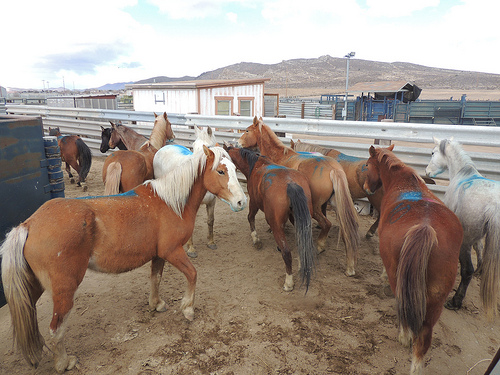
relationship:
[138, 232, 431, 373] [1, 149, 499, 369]
footprints in dirt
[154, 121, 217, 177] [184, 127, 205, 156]
horse has light hair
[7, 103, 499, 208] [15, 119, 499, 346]
fence by horses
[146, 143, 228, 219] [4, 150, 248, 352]
mane of horse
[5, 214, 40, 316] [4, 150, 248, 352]
tail of horse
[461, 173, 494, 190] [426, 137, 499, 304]
paint on horse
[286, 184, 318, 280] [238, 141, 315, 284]
tail of horse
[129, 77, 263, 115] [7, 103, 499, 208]
building behind fence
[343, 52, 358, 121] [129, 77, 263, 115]
lamp post behind building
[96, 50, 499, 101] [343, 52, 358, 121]
mountains behind lamp post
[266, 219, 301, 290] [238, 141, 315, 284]
leg of a horse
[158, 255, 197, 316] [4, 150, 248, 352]
leg of a horse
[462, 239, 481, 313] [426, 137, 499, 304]
leg of a horse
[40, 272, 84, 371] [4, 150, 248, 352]
leg of a horse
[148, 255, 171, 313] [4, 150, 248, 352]
leg of a horse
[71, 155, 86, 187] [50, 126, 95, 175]
leg of a horse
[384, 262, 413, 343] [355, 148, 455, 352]
leg of a horse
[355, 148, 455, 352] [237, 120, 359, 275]
horse next to horse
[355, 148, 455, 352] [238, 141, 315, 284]
horse next to horse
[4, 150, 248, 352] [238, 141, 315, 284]
horse next to horse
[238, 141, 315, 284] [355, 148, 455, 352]
horse next to horse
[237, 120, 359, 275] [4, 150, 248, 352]
horse next to horse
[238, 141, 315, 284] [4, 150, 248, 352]
horse next to horse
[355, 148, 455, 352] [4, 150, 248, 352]
horse next to horse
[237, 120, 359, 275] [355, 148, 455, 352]
horse next to horse